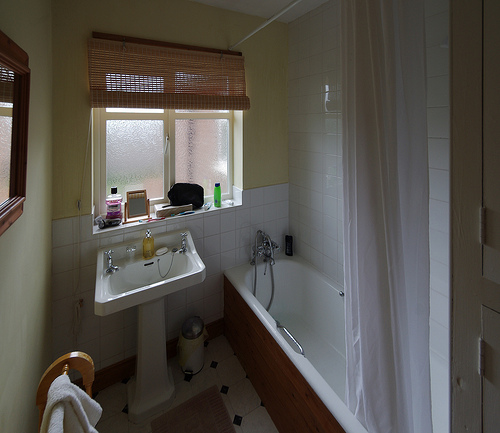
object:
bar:
[155, 247, 168, 256]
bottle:
[106, 186, 123, 221]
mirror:
[128, 199, 148, 217]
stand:
[123, 195, 156, 226]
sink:
[95, 230, 207, 317]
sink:
[93, 237, 199, 298]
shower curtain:
[336, 2, 433, 432]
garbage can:
[177, 315, 206, 374]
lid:
[181, 311, 206, 341]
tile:
[99, 333, 261, 431]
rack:
[37, 348, 99, 430]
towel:
[35, 373, 103, 432]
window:
[94, 55, 240, 212]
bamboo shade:
[87, 39, 250, 110]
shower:
[214, 182, 221, 208]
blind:
[89, 46, 249, 111]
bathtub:
[222, 247, 382, 433]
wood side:
[219, 280, 347, 433]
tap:
[175, 232, 190, 255]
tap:
[103, 247, 119, 274]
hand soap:
[142, 229, 154, 260]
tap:
[252, 227, 279, 266]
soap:
[155, 249, 171, 257]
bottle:
[142, 229, 154, 259]